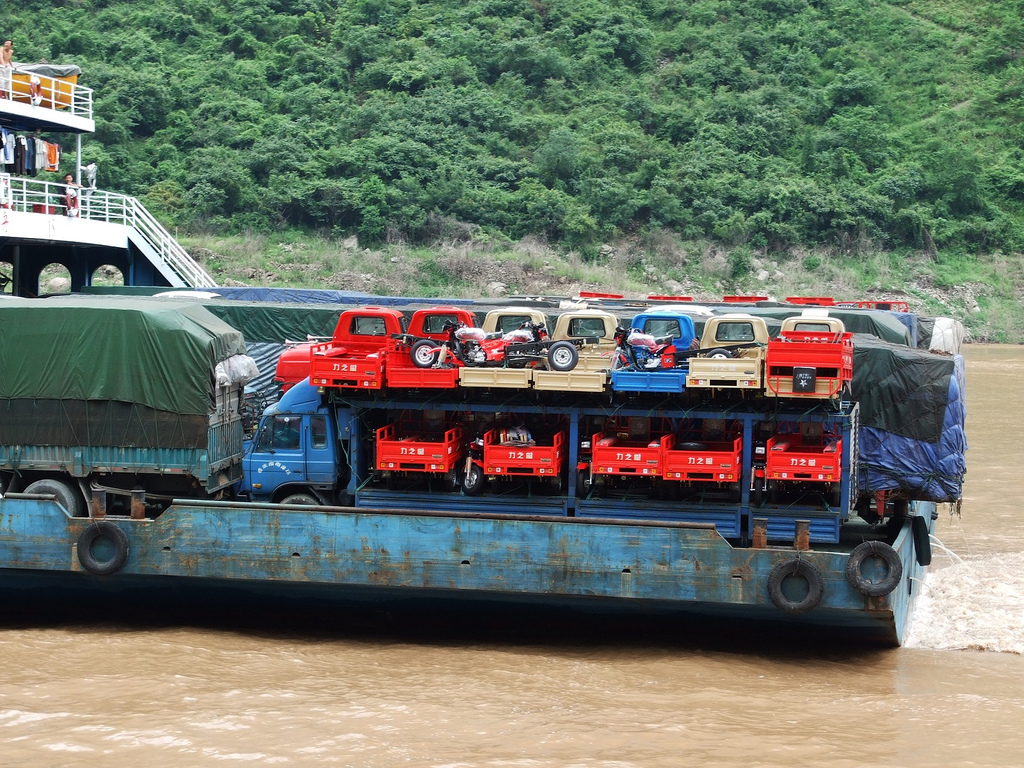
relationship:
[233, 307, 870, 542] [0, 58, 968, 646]
truck on ship